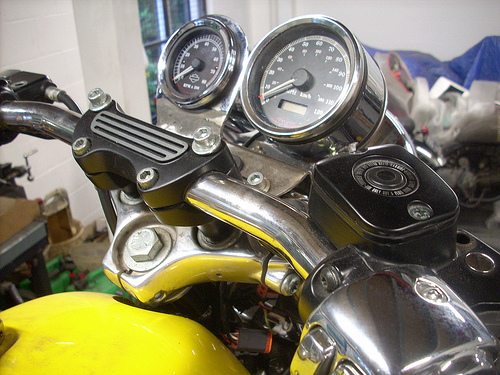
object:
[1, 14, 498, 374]
motorcycle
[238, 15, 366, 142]
speedometer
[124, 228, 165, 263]
bolt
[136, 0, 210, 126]
window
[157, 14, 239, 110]
tachometer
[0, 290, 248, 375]
petrol tank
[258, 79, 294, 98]
needle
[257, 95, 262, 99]
tip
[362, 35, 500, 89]
tarp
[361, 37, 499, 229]
area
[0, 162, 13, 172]
vice grip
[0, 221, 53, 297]
work bench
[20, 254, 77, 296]
supplies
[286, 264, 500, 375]
handles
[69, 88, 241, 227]
clamp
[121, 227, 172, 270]
washer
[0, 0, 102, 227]
wall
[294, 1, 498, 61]
rear wall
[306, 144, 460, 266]
box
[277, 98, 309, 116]
odometer